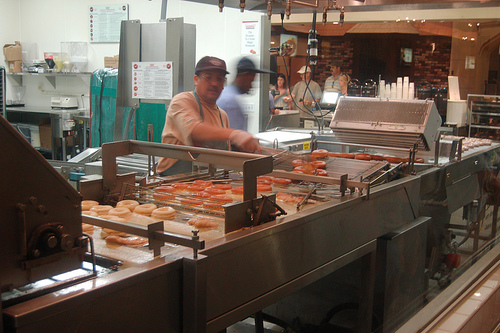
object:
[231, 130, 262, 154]
hand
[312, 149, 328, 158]
doughnuts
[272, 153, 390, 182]
tray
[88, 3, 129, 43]
sign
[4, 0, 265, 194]
wall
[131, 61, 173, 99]
sign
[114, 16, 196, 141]
equipment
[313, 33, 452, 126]
entrance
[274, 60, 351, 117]
customer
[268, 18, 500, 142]
background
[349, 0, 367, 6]
lights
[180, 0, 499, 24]
ceiling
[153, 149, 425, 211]
doughnuts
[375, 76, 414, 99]
cups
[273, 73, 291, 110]
customer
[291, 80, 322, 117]
shirt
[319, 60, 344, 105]
man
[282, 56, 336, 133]
wire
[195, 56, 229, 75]
hat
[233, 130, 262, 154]
glove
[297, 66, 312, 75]
hat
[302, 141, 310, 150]
label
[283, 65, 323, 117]
person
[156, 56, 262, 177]
conveyor